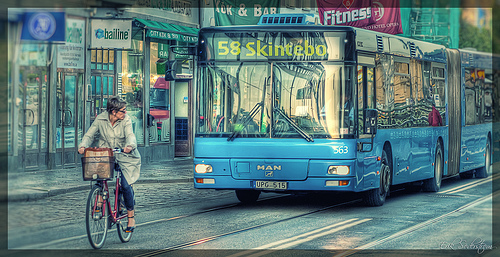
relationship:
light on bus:
[194, 163, 215, 174] [195, 25, 496, 195]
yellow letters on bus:
[212, 41, 332, 58] [195, 25, 496, 195]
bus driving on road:
[195, 25, 496, 195] [9, 176, 498, 253]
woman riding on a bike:
[83, 99, 142, 176] [81, 174, 136, 242]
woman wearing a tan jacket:
[83, 99, 142, 176] [83, 114, 142, 181]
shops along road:
[7, 10, 197, 163] [9, 176, 498, 253]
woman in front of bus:
[83, 99, 142, 176] [195, 25, 496, 195]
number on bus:
[214, 40, 247, 60] [195, 25, 496, 195]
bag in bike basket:
[88, 150, 110, 179] [79, 153, 114, 178]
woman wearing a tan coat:
[83, 99, 142, 176] [83, 114, 142, 181]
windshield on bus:
[196, 68, 357, 138] [195, 25, 496, 195]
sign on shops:
[88, 20, 132, 45] [7, 10, 197, 163]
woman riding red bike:
[83, 99, 142, 176] [81, 174, 136, 242]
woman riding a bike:
[83, 99, 142, 176] [81, 174, 136, 242]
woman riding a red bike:
[83, 99, 142, 176] [81, 174, 136, 242]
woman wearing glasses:
[83, 99, 142, 176] [114, 110, 128, 114]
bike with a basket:
[81, 174, 136, 242] [79, 153, 114, 178]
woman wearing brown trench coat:
[83, 99, 142, 176] [83, 114, 142, 181]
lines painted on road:
[247, 217, 363, 247] [9, 176, 498, 253]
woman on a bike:
[83, 99, 142, 176] [81, 174, 136, 242]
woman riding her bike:
[83, 99, 142, 176] [81, 174, 136, 242]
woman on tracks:
[83, 99, 142, 176] [166, 199, 237, 241]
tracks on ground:
[166, 199, 237, 241] [9, 176, 498, 253]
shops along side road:
[7, 10, 197, 163] [9, 176, 498, 253]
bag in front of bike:
[88, 150, 110, 179] [81, 174, 136, 242]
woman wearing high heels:
[83, 99, 142, 176] [124, 215, 139, 235]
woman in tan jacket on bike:
[83, 99, 142, 176] [81, 174, 136, 242]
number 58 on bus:
[214, 40, 247, 60] [195, 25, 496, 195]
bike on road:
[81, 174, 136, 242] [9, 176, 498, 253]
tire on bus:
[371, 156, 392, 198] [195, 25, 496, 195]